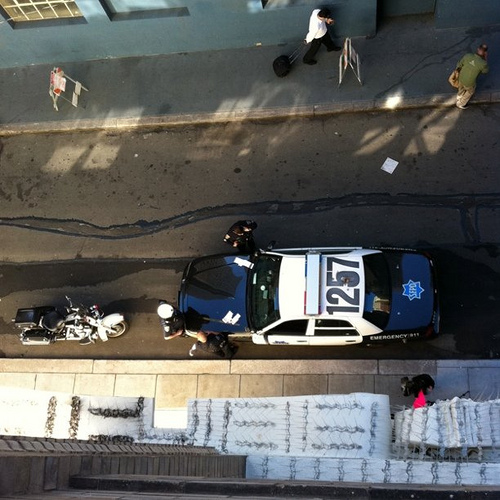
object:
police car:
[173, 238, 443, 348]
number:
[324, 288, 358, 307]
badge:
[401, 278, 425, 301]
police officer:
[155, 297, 188, 341]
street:
[0, 102, 499, 361]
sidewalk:
[0, 356, 499, 428]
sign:
[44, 66, 89, 112]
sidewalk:
[0, 25, 500, 135]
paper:
[380, 157, 397, 175]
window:
[0, 1, 88, 33]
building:
[0, 0, 499, 70]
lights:
[303, 250, 318, 317]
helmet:
[156, 303, 174, 319]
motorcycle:
[9, 293, 127, 348]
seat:
[42, 311, 67, 331]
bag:
[273, 54, 291, 76]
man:
[304, 7, 332, 65]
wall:
[0, 0, 379, 69]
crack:
[76, 243, 97, 258]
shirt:
[455, 51, 491, 90]